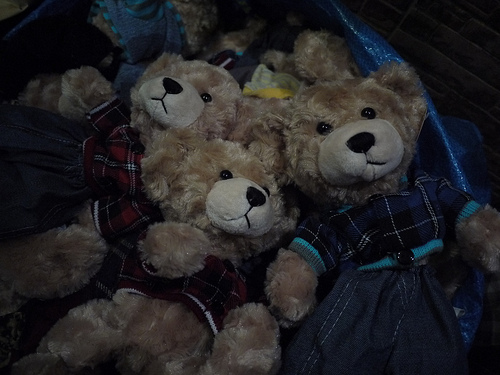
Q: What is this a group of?
A: Teddy bears.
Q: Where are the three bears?
A: In a group.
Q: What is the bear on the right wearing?
A: Pants.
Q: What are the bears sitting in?
A: A bag.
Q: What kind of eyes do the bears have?
A: Dark.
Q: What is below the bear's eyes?
A: Nose.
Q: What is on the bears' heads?
A: Ears.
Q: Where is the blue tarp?
A: Under the bears.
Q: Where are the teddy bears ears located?
A: On the side of their heads.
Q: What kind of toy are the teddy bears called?
A: Stuffed animals.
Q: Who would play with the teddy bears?
A: Children.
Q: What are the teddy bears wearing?
A: Clothes.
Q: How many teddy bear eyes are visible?
A: Five.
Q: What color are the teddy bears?
A: Brown.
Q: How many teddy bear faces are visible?
A: Three.